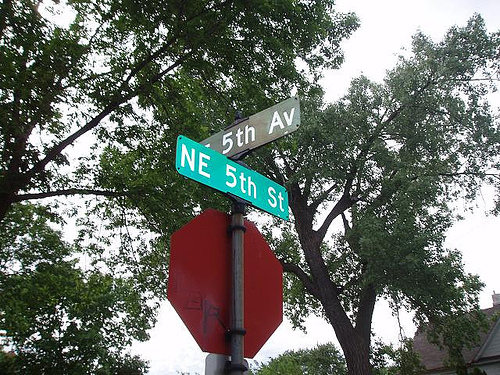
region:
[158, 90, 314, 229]
street signs posted at intersection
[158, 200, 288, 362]
back of stop sign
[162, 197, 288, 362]
red painted sign back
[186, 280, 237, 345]
graffiti on back of stop sign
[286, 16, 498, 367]
top of tree with large branches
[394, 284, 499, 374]
roof top seen behind tree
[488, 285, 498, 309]
chimney on roof of house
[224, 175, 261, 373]
post signs are mounted on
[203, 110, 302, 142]
street sign painted black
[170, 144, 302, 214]
street sign painted green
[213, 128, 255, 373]
The pole is straight.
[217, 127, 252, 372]
The pole is metal.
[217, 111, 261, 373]
The pole is silver.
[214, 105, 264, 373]
Pole has signs attached.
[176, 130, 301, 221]
The sign is green.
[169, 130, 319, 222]
The sign is rectangular.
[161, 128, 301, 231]
The sign has lettering.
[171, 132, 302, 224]
The lettering is white.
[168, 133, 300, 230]
Sign has number on it.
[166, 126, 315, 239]
Number five on a sign.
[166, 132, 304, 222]
THE SIGN IS GREEN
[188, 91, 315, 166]
THE SIGN IS DARK GREY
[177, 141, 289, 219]
THE SIGN SAYS NE 5TH ST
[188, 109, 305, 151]
THE SIGN SAYS 5TH AV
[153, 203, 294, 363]
THE SIGN IS RED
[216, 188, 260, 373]
THE POLE IS BLACK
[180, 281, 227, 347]
THE SIGN HAS GRAFFITI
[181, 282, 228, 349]
THE GRAFFITI IS BLACK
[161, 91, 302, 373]
THE SIGNS ARE TOGETHER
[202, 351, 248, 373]
THE SIGN IS WHITE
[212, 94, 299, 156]
a faded green street sign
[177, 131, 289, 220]
a green street sign displaying NE 5th street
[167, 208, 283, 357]
the back of a stop sign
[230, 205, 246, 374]
a metal street sign pole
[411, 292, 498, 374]
a home across the street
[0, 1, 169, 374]
tall trees along the street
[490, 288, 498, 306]
a white bucket on the roof of the house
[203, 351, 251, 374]
a street sign on the bottom of the pole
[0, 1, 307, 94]
light through the tree branches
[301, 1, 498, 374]
large tree in front of the house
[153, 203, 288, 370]
the sign is red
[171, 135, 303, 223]
the sign is green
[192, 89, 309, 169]
the sign is dark grey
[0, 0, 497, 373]
the trees are big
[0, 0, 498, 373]
the sky is white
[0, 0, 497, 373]
the sky is hazy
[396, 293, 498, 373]
the roof of a house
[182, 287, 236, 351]
the sign has graffiti on it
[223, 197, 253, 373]
the post is holding the sign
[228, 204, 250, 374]
the post is black